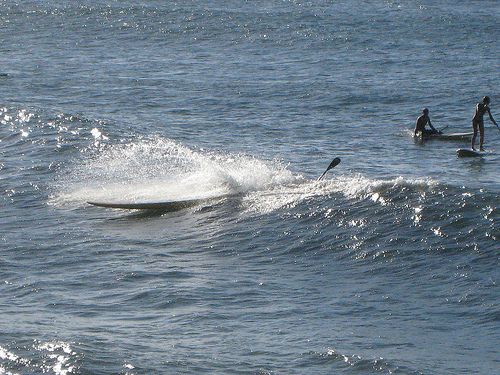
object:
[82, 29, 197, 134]
water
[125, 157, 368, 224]
wave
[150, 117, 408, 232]
wave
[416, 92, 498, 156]
people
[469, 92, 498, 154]
person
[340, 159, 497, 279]
water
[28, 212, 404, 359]
ripples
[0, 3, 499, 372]
ocean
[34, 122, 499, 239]
wave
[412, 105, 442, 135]
person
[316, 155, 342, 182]
paddle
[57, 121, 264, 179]
splash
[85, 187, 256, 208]
surfboard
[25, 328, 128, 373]
wave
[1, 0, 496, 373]
water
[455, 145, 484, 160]
surfboard